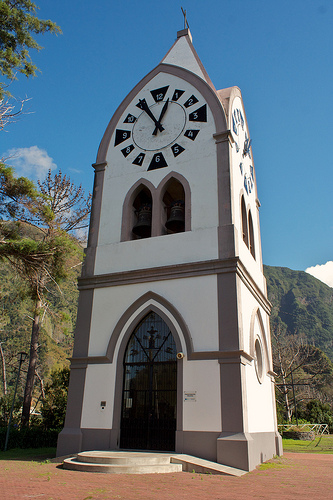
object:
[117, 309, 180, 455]
doorway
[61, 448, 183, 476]
step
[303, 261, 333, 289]
cloud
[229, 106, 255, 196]
clock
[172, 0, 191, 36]
cross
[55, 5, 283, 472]
building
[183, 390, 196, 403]
sign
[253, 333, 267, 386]
window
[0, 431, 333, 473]
grass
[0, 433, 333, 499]
ground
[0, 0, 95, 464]
tree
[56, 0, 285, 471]
tower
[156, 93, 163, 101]
number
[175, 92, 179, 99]
number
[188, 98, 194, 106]
number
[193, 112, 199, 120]
number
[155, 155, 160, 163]
number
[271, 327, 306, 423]
tree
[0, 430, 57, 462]
shade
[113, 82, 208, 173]
clock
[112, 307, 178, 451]
door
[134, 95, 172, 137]
hands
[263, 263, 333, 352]
hill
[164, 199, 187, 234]
bell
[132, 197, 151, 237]
bell